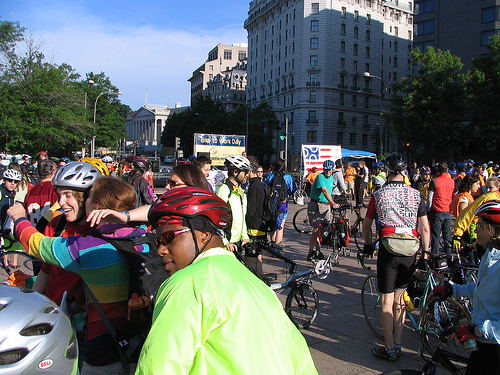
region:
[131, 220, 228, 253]
red and black goggles on man's face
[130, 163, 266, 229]
red and black shiny helmet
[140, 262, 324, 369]
man wearing shiny lime green jacket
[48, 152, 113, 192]
silver helmet on woman's head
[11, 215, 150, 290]
multi colored jacket on woman's back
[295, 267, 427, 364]
shadow cast on the ground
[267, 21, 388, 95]
large white building in the background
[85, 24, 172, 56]
soft white clouds in the sky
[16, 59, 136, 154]
large cluster of green trees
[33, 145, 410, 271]
people standing in the street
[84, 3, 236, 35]
this is the sky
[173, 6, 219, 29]
the sky is blue in color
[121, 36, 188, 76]
these are the clouds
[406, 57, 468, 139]
this is a tree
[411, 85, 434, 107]
the tree has green leaves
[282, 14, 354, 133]
this is a building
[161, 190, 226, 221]
this is an heklmet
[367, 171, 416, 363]
this is a man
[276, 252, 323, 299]
this is a bicycle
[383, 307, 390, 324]
the man is light skinned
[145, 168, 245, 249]
red and black bike helmet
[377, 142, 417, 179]
black bike helmet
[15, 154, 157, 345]
two people hugging at bike race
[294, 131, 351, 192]
red white and blue banner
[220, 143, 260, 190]
white and black bike helmet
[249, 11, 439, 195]
tall building with many levels of windows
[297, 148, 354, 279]
man in blue shirt and helmet pushing his bike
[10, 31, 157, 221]
tall trees with lots of green leaves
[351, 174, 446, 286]
red black and white bike shirt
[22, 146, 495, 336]
large crowd at bike race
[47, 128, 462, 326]
A crowd of people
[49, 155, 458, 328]
A crowd of people with bikes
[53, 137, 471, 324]
A crowd of people with helmets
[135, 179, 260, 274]
A red bike helmet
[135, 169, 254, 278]
A man wearing a red bike helmet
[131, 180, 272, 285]
A man wearing red sun glasses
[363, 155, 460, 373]
A man with a bike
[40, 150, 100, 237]
A person wearing a silver helmet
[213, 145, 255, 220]
A person wearing a white helmet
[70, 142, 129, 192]
A yellow helmet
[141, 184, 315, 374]
man wearing red helmet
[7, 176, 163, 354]
woman wearing multicolored shirt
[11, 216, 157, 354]
shirt with stripes of several colors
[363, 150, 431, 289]
man wearing black biking shorts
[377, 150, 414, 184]
man wearing black helmet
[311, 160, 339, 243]
man wearing teal shirt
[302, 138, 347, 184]
white sign with red stripes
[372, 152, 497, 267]
large gathering of bicyclists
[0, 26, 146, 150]
tall green trees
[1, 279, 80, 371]
silver aerated helmet